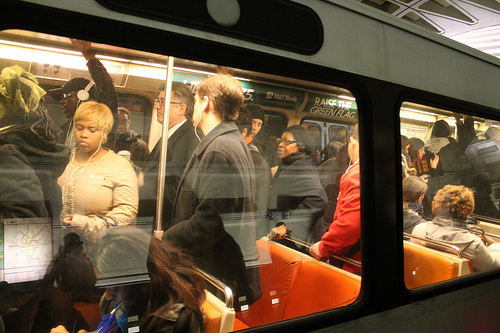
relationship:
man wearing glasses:
[138, 83, 203, 235] [153, 98, 183, 105]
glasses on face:
[153, 98, 183, 105] [153, 92, 170, 122]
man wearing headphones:
[153, 72, 271, 312] [184, 94, 214, 146]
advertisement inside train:
[300, 92, 362, 126] [0, 0, 500, 333]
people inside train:
[0, 35, 499, 331] [0, 0, 500, 333]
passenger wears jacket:
[308, 122, 361, 276] [314, 159, 363, 268]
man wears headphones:
[161, 74, 255, 312] [193, 102, 207, 142]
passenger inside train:
[408, 181, 498, 279] [5, 0, 495, 327]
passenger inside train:
[418, 116, 462, 168] [5, 0, 495, 327]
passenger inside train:
[307, 122, 367, 256] [5, 0, 495, 327]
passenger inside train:
[271, 121, 332, 245] [5, 0, 495, 327]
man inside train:
[161, 74, 255, 312] [5, 0, 495, 327]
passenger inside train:
[410, 184, 500, 271] [5, 0, 495, 327]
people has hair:
[57, 101, 140, 243] [67, 99, 115, 142]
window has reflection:
[5, 33, 370, 325] [31, 143, 340, 258]